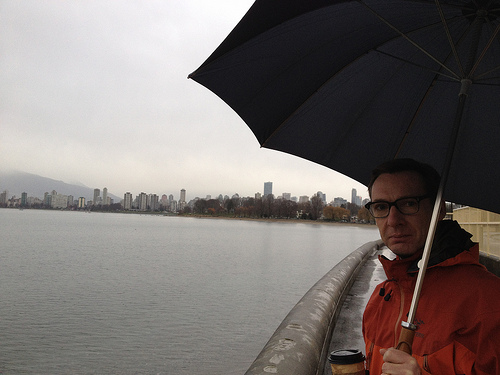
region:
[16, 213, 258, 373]
A calm body of water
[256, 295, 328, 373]
A gray concrete barrier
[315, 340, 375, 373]
A disposable coffee cup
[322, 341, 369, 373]
A coffe cup with a black plastic lid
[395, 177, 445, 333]
A silver metal umbrella pole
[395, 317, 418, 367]
A silver and brown umbrella handle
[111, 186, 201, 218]
A group of buildings in a city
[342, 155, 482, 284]
A man wearing eyeglasses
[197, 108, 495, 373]
A man holding an umbrella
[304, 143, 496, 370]
A man wearing an orange jacket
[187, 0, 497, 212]
black umbrella is open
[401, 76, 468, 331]
silver umbrella pole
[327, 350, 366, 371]
disposable coffee cup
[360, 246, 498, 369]
orange zip up rain coat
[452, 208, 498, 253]
tan railing behind the man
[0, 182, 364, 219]
tall buildings on the horizon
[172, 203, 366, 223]
brown trees in front of the buildings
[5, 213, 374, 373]
a large body of water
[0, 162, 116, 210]
fog covered mountain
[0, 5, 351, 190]
skies are overcast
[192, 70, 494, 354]
a person holding an umbrella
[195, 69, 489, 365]
a person standing under an umbrella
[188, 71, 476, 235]
an umbrella shielding a person.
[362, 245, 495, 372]
a person wearing an orange jacket.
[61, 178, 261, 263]
a city near a body of water.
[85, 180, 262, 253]
a city near a huge lake.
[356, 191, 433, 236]
a person wearing black glasses.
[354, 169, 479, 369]
a person standing near a lake.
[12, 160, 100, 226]
A mountain surrounding a city.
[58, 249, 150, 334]
Part of the water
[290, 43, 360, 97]
Part of the black umbrella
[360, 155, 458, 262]
The head of the person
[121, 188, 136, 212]
A building in distance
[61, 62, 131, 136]
Part of the sky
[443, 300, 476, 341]
Part of the orange jacket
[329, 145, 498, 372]
A person standing near the water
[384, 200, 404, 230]
The nose of the person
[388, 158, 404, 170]
Part of the person's hair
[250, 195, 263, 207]
Part of the trees in distance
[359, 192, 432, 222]
a person wearing eyeglass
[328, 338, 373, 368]
a top of the bottle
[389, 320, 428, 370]
a prson holding wooden handle umbrella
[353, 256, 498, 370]
a person wearing orange color jacket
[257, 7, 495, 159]
black color umbrella with spokes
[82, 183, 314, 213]
buildings behind the water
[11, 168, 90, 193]
mountain with mists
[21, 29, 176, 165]
sky with full of clouds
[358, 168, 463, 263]
a man is looking at the camera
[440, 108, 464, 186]
silver stick of the umbrella